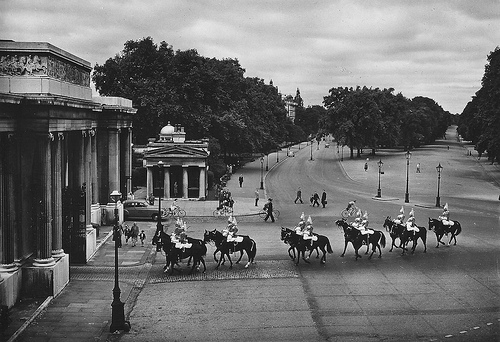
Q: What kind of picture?
A: Black and white.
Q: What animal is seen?
A: Horses.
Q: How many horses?
A: 11.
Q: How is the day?
A: Cloudy.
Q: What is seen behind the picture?
A: Trees.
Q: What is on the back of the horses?
A: Men are sitting on the horse.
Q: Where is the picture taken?
A: At the horse March.